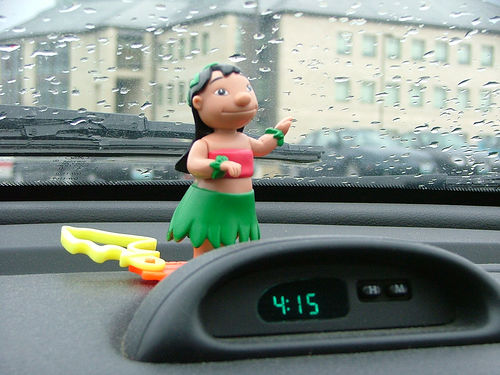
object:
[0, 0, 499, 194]
windshield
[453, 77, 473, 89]
raindrop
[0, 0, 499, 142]
building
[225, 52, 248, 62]
drop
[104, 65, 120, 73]
water droplet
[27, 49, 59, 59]
water